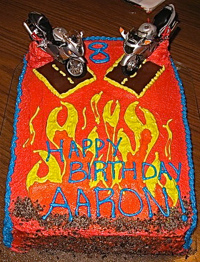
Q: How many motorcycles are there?
A: 2.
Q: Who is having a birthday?
A: Aaron.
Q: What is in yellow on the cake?
A: Flames.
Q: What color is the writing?
A: Blue.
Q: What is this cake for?
A: Birthday.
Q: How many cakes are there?
A: 1.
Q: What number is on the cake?
A: 8.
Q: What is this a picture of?
A: Cake.